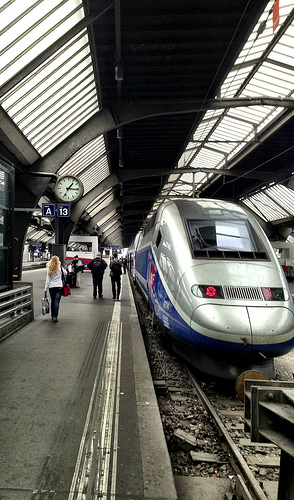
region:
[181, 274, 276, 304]
red lights on the train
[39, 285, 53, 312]
woman is carrying a bag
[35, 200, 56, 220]
A is on a blue sign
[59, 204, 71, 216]
13 on a blue sign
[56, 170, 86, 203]
clock above the signs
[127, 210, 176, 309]
blue and silver on the train colors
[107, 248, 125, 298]
passenger of the train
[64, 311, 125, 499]
white line next to the train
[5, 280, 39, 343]
railing next to walkway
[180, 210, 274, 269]
window on the train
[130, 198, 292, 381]
A grey and blue train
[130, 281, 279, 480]
some gravel on the ground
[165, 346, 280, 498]
some railroad tracks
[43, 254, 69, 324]
A woman in a white shirt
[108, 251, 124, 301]
a man in a grey shirt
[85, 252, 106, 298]
a man in a black jacket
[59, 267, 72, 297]
A red bag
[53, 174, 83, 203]
clock hanging from the wall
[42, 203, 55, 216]
A blue and white sign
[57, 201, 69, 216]
A blue and white sign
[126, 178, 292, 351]
train on the tracks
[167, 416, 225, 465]
debris on the tracks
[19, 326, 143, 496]
the platform beside the tracks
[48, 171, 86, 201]
the clock on the wall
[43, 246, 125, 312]
passengers on the platform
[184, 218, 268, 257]
windshield of the train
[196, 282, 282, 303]
lights on the train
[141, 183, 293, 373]
the train is silver and blue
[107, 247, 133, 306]
the person walking with backpack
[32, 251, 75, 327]
the woman with the red bag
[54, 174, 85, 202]
round clock showing 1:15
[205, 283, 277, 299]
two red lights on train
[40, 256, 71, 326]
blonde woman in white shirt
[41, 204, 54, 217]
white "A" on blue background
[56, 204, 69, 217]
white "13" on blue background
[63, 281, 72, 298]
red bag carried by blonde woman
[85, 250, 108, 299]
man with gray hair facing away from camera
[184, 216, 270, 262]
windshield of train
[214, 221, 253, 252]
relfection of ceiling window in train windshield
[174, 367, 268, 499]
track in front of train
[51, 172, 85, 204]
clock giving the time as one-fifteen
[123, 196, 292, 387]
blue and silver Amtrak train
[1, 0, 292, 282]
steel beam reinforced ceiling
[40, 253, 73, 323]
woman carrying a piece of red luggage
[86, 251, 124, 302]
two men walking side-by-side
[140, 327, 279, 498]
railroad tracks with rock bedding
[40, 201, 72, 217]
two royal blue signs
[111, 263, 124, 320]
white line painted at side of curbing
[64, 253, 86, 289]
two people with luggage and packages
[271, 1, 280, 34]
red flag hanging from ceiling